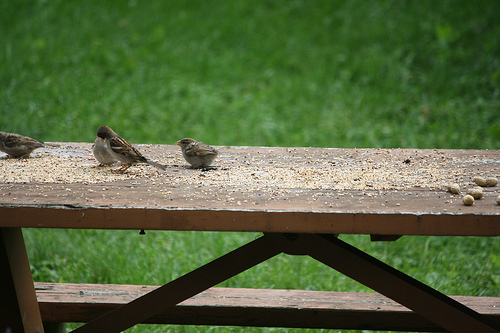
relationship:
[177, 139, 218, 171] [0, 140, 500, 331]
bird on top of picnic table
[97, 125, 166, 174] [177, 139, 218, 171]
bird near bird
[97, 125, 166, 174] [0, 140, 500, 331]
bird standing on picnic table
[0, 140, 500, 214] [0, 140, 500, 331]
bird seed on top of picnic table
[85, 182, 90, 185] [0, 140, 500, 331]
bird seed on top of picnic table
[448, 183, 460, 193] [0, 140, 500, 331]
peanut on top of picnic table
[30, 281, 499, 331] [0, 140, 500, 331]
bench behind picnic table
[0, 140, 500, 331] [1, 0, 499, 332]
picnic table on top of lawn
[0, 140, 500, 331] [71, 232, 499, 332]
picnic table has support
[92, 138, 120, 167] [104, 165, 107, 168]
bird standing on bird seed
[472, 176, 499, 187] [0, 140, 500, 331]
peanut on top of picnic table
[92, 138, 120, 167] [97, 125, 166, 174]
bird behind bird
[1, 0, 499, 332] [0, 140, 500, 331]
lawn below picnic table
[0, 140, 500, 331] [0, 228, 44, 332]
picnic table has leg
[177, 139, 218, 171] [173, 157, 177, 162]
bird eating bird seed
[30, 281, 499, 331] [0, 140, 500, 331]
bench below picnic table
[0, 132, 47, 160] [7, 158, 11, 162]
bird standing near bird seed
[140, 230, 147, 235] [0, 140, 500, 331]
nail on underside of picnic table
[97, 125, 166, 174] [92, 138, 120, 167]
bird near bird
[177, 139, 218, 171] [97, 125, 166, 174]
bird near bird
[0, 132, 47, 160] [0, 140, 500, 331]
bird standing on picnic table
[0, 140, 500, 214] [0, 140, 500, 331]
bird seed on picnic table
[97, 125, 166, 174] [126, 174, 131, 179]
bird standing near bird seed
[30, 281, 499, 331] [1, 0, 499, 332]
bench on top of lawn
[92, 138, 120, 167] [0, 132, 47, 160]
bird near bird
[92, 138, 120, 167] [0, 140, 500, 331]
bird on top of picnic table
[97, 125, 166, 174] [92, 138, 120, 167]
bird standing near bird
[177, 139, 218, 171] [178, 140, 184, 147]
bird has beak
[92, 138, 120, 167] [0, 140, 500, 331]
bird sitting on picnic table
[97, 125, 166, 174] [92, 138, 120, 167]
bird eating near bird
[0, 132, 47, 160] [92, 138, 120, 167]
bird near bird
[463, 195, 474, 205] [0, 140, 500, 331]
peanut on top of picnic table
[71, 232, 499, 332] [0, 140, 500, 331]
support under picnic table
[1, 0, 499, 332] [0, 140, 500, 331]
lawn behind picnic table